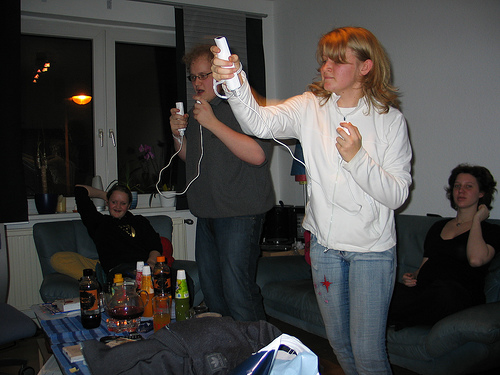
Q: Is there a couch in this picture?
A: Yes, there is a couch.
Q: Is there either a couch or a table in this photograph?
A: Yes, there is a couch.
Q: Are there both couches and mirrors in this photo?
A: No, there is a couch but no mirrors.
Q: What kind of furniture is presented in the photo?
A: The furniture is a couch.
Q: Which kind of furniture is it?
A: The piece of furniture is a couch.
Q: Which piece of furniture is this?
A: This is a couch.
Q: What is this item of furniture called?
A: This is a couch.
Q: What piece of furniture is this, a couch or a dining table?
A: This is a couch.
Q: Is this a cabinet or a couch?
A: This is a couch.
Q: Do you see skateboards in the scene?
A: No, there are no skateboards.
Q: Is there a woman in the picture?
A: Yes, there is a woman.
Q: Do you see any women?
A: Yes, there is a woman.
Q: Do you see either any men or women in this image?
A: Yes, there is a woman.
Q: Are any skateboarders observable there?
A: No, there are no skateboarders.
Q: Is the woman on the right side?
A: Yes, the woman is on the right of the image.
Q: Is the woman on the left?
A: No, the woman is on the right of the image.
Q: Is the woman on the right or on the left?
A: The woman is on the right of the image.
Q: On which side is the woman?
A: The woman is on the right of the image.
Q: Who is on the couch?
A: The woman is on the couch.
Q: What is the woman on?
A: The woman is on the couch.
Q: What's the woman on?
A: The woman is on the couch.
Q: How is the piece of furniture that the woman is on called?
A: The piece of furniture is a couch.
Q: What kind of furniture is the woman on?
A: The woman is on the couch.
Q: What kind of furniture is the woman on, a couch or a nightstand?
A: The woman is on a couch.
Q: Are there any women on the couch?
A: Yes, there is a woman on the couch.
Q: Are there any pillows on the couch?
A: No, there is a woman on the couch.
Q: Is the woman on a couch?
A: Yes, the woman is on a couch.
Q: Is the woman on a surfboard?
A: No, the woman is on a couch.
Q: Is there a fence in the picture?
A: No, there are no fences.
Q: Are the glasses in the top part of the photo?
A: Yes, the glasses are in the top of the image.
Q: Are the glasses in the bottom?
A: No, the glasses are in the top of the image.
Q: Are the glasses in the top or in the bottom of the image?
A: The glasses are in the top of the image.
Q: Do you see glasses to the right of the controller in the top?
A: Yes, there are glasses to the right of the controller.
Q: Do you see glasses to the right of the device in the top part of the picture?
A: Yes, there are glasses to the right of the controller.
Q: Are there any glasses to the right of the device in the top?
A: Yes, there are glasses to the right of the controller.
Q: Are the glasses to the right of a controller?
A: Yes, the glasses are to the right of a controller.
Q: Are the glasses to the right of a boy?
A: No, the glasses are to the right of a controller.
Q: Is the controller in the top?
A: Yes, the controller is in the top of the image.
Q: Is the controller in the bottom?
A: No, the controller is in the top of the image.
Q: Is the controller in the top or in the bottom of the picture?
A: The controller is in the top of the image.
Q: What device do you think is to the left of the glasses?
A: The device is a controller.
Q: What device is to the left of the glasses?
A: The device is a controller.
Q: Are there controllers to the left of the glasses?
A: Yes, there is a controller to the left of the glasses.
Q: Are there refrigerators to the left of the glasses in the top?
A: No, there is a controller to the left of the glasses.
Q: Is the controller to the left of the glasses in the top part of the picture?
A: Yes, the controller is to the left of the glasses.